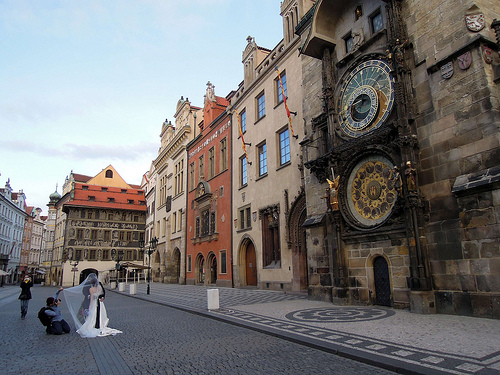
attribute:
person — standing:
[16, 274, 35, 319]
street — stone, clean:
[4, 280, 407, 372]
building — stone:
[291, 7, 499, 312]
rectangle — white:
[204, 286, 224, 312]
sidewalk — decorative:
[114, 277, 500, 373]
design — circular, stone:
[274, 299, 402, 327]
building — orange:
[186, 93, 231, 287]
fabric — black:
[96, 274, 108, 332]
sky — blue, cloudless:
[2, 5, 243, 188]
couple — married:
[63, 268, 133, 340]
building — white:
[137, 163, 159, 283]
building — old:
[66, 165, 149, 282]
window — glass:
[365, 9, 393, 33]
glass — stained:
[372, 20, 385, 29]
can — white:
[201, 281, 230, 316]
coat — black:
[19, 281, 33, 300]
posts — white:
[121, 269, 150, 284]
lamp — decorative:
[137, 235, 164, 297]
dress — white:
[77, 291, 121, 336]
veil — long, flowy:
[60, 272, 99, 326]